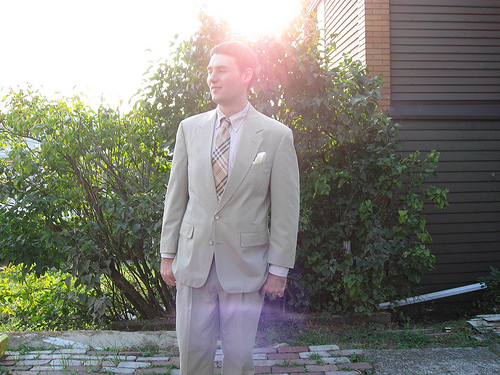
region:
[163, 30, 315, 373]
man in tan dress suit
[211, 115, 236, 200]
burberry plaid patterned tie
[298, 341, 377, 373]
brick layered sidewalk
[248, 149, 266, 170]
pocket square coming out of jacket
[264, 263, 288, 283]
sleeve coming out of tan jacket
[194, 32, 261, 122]
head looking toward left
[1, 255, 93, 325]
green grass with sun reflection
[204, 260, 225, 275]
bottom button left unbuttoned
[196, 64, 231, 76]
set of 2 eyes on person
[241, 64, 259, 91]
left ear of person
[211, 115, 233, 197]
the brown and tan tie of the man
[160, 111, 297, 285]
the tan suit coat of the man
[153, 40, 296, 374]
the suited man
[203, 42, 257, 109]
the head of the man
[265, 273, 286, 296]
the hand of the man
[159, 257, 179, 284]
the hand of the man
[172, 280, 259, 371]
the tan suit pants of the man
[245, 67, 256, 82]
the ear of the man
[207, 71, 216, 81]
the nose of the man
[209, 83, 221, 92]
the mouth of the man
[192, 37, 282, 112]
a man with red hair.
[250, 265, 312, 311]
the hand of a man.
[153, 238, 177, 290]
the right hand of a man.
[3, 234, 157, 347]
a lush green yard.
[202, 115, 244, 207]
a neck tie on a man.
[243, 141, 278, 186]
a hankee in a pocket.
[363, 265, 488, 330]
a hand rail on a walkway.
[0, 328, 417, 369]
a brick walkway.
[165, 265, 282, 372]
beige pants on a man.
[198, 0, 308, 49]
the bright sun over a house.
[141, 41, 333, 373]
man in a suit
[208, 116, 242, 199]
plaid tie worn by man in the suit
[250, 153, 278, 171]
white handkerchief in the pocket of the suit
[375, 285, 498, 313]
rain gutter on the side of the house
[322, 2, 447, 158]
side of the house behind the the man in the suit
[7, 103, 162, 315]
bush in the yard behind the man in the suit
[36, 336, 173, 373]
bricks on the ground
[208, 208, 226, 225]
button on the jacket of the suit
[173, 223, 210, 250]
pocket on the front of the suit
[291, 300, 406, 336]
bricks around the bush in the yard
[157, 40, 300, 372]
a young man in a suit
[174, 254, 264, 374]
pleated khaki pants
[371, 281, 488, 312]
a white rain gutter in front of a house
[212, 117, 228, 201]
a light-colored plaid tie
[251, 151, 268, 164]
a white, wrinkled pocket square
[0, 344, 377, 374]
a crooked brick pathway behind a man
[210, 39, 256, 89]
a short brunette hairstyle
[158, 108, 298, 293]
a khaki suit jacket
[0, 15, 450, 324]
small green trees behind a man in a suit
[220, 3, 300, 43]
a bright sun above green trees